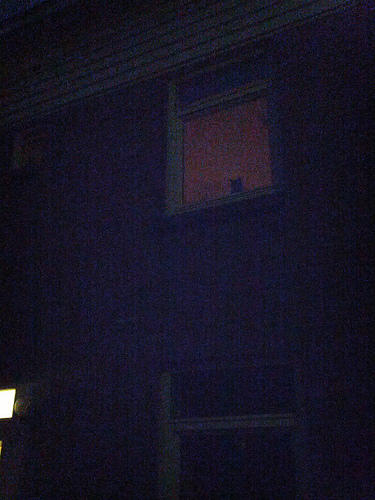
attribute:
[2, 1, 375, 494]
building — tall, nightime, dark, grainy, large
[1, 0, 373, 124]
roof — black, shingled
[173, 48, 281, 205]
window — white, lit, bright, light, dark, open, dim, paned, framed, silled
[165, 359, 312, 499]
door — dark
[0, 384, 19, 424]
light — bright, on